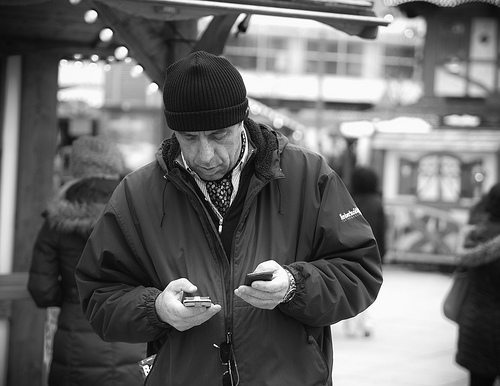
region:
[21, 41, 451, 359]
A man is checking his phone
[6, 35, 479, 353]
A man is sending a text message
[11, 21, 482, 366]
The man is reading a text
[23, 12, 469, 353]
The man is holding two phones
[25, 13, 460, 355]
The man is wearing a heavy jacket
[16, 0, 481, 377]
The man is wearing a stocking cap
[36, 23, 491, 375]
The man is in the city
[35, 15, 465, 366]
The man is waiting for a friend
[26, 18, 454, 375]
The man is on a sidewalk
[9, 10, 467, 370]
The man is going to have lunch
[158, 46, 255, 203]
Man with a hat on his head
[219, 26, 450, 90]
Three windows on a building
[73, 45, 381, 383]
Man is holding two cell phones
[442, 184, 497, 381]
A person carrying a bag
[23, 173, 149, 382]
A heavy winter jacket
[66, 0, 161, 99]
Lights on an awning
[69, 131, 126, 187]
Bonnet on a person's head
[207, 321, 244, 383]
Sunglasses hanging from a jacket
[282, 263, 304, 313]
A watch around a man's wrist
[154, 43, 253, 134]
A black knitted hat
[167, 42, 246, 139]
hat on the man's head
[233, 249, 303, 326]
hand of the man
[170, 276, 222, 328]
object in man's hand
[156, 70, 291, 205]
man looking down at something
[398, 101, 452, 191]
blurry background of the photo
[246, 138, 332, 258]
jacket on the man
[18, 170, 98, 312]
jacket on the person behind the man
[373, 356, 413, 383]
ground in the photo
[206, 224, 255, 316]
zipper on man's jacket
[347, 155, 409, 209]
person in the distance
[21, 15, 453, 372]
A man is checking his cell phone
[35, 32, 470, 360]
A man is placing a call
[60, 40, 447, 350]
A man is checking his messages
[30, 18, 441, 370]
A man is saving a phone number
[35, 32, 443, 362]
A man is holding two cell phones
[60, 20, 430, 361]
A man is wearing a stocking cap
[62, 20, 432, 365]
A man is wearing a heavy jacket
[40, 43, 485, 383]
A man is in the city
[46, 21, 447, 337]
A man is on the sidewalk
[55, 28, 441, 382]
A man is waiting for a bus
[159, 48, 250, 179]
Hat on a man's head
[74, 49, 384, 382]
A man looking at two cell phones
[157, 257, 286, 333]
Two cell phones in two hands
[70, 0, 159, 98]
Lights on a building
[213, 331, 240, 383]
Glasses attached to a jacket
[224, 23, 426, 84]
Windows on a building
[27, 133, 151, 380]
Person wearing a winter jacket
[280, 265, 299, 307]
Watch around a wrist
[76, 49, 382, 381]
Man is wearing a jacket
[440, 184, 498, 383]
Person is carrying a bag